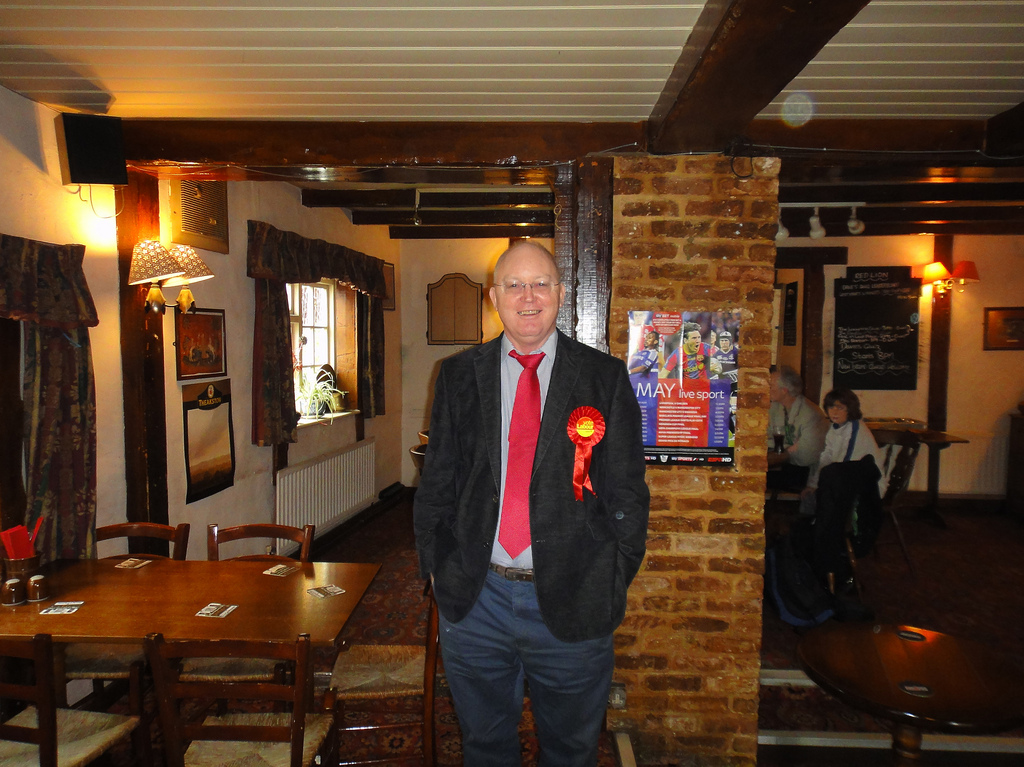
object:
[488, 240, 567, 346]
head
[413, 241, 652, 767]
man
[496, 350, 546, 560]
tie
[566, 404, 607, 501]
ribbon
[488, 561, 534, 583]
belt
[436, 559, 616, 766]
pants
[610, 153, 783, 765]
wall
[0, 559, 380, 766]
table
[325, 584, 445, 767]
chair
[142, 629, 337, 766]
chair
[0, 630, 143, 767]
chair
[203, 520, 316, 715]
chair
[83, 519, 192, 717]
chair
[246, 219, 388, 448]
drapes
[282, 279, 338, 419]
window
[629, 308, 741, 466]
poster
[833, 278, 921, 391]
board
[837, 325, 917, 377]
writing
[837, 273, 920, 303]
writing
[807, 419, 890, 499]
shirt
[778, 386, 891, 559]
woman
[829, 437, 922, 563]
chair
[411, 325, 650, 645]
jacket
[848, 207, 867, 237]
light fixture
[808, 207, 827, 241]
light fixture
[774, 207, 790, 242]
light fixture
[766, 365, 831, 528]
man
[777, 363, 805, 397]
hair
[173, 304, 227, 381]
painting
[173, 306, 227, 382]
frame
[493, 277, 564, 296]
glasses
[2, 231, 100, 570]
curtains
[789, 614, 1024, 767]
table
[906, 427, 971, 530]
table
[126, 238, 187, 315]
light fixture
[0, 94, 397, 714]
wall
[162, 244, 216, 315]
light fixture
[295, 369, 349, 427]
plant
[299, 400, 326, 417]
pot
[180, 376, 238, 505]
picture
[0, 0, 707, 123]
ceiling panels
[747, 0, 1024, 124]
ceiling panels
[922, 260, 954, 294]
light fixture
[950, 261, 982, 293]
light fixture